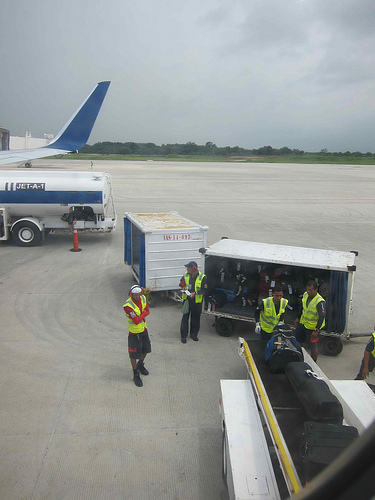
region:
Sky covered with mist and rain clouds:
[0, 0, 374, 143]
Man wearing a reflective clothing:
[122, 282, 157, 388]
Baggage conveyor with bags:
[238, 334, 361, 499]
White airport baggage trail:
[121, 209, 362, 358]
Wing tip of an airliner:
[0, 78, 111, 169]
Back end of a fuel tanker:
[0, 165, 118, 248]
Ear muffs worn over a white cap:
[125, 283, 144, 299]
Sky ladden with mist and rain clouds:
[0, 1, 374, 153]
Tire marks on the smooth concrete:
[7, 264, 125, 374]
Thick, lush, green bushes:
[80, 136, 374, 157]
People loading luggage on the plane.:
[221, 276, 336, 354]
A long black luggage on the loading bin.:
[280, 359, 341, 420]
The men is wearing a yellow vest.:
[254, 293, 339, 328]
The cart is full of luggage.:
[216, 268, 314, 306]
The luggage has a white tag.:
[306, 365, 330, 385]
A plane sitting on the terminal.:
[22, 112, 112, 173]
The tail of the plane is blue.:
[52, 90, 118, 161]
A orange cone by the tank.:
[38, 186, 101, 267]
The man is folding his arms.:
[117, 293, 167, 323]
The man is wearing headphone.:
[118, 281, 152, 298]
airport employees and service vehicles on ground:
[10, 116, 359, 476]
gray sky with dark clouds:
[144, 22, 358, 114]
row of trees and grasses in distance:
[85, 135, 365, 166]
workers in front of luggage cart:
[175, 245, 355, 344]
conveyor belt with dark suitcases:
[245, 333, 350, 484]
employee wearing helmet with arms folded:
[25, 265, 162, 479]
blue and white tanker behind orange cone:
[1, 159, 111, 254]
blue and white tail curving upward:
[3, 69, 118, 166]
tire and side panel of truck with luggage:
[215, 372, 275, 489]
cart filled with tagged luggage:
[203, 234, 353, 328]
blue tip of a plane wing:
[50, 78, 112, 149]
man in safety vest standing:
[120, 284, 152, 384]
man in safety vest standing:
[178, 261, 202, 346]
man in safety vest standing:
[297, 283, 323, 362]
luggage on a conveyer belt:
[286, 360, 341, 420]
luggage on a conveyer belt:
[264, 325, 303, 370]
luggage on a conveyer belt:
[301, 419, 360, 480]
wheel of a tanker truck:
[12, 222, 40, 244]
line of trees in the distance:
[87, 141, 373, 163]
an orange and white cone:
[68, 218, 81, 251]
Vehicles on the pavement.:
[131, 179, 336, 330]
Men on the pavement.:
[99, 242, 312, 395]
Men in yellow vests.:
[75, 246, 327, 442]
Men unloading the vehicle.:
[164, 235, 374, 413]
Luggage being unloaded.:
[227, 313, 353, 474]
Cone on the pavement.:
[61, 200, 156, 308]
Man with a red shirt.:
[96, 271, 179, 422]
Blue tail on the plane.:
[39, 75, 138, 167]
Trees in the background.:
[111, 101, 303, 193]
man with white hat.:
[120, 283, 173, 329]